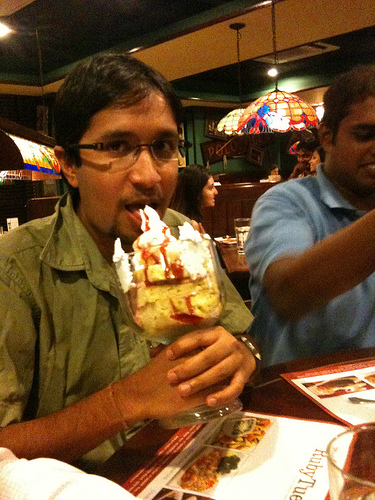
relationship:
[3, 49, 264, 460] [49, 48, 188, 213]
boy has hair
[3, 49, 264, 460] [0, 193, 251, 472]
boy has shirt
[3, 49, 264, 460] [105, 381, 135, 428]
boy wearing bracelet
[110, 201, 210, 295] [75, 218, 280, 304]
whipped cream on cake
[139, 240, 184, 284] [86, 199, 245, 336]
syrup on cake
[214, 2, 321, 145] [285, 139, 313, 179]
lamp behind boy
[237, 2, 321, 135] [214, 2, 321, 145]
lamp behind lamp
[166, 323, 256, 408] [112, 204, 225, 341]
hand holding ice cream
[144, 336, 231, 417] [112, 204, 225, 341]
hand holding ice cream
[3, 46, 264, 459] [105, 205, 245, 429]
boy enjoying ice cream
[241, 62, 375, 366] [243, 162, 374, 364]
boy in blue shirt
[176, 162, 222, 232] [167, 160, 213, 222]
woman with hair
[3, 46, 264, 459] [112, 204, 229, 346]
boy eating cake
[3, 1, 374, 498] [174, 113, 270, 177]
restaurant has decorations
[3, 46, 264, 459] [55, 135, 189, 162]
boy has glasses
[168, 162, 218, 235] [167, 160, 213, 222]
woman has hair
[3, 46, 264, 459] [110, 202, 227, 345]
boy enjoying ice cream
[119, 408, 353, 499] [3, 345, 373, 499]
paper on table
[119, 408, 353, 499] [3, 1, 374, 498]
paper showing restaurant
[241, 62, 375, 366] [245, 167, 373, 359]
boy in shirt